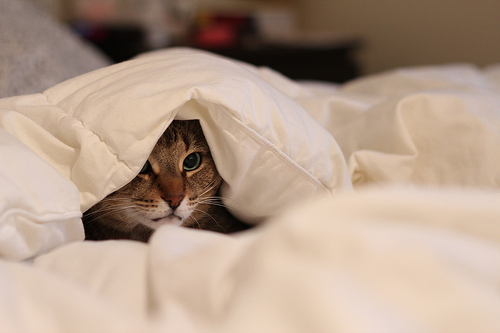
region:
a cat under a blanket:
[90, 107, 237, 230]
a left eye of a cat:
[181, 147, 203, 172]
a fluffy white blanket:
[15, 62, 488, 227]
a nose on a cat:
[163, 192, 188, 205]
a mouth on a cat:
[146, 208, 181, 225]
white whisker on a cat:
[88, 195, 138, 230]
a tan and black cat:
[96, 113, 228, 233]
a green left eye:
[181, 145, 206, 173]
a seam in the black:
[46, 80, 96, 160]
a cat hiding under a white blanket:
[0, 60, 489, 324]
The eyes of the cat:
[135, 153, 220, 188]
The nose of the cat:
[165, 183, 179, 204]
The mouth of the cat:
[157, 211, 188, 221]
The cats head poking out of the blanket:
[85, 135, 239, 220]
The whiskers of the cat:
[97, 195, 217, 216]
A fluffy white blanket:
[5, 68, 429, 330]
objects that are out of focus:
[46, 2, 348, 110]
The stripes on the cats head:
[159, 133, 196, 143]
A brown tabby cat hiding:
[109, 148, 234, 246]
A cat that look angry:
[73, 131, 248, 251]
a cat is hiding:
[81, 118, 253, 241]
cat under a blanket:
[81, 118, 255, 242]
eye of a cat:
[183, 148, 203, 171]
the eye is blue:
[182, 148, 204, 174]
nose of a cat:
[165, 194, 183, 204]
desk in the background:
[170, 36, 365, 82]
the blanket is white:
[0, 49, 495, 329]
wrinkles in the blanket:
[348, 65, 496, 180]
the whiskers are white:
[192, 179, 226, 223]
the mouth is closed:
[150, 209, 185, 223]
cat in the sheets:
[99, 84, 265, 239]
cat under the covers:
[55, 89, 296, 259]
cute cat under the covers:
[46, 75, 332, 278]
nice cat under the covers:
[42, 82, 302, 256]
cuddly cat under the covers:
[32, 66, 307, 281]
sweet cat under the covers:
[52, 72, 292, 276]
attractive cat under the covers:
[37, 95, 287, 282]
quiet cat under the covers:
[55, 75, 300, 274]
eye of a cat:
[166, 146, 215, 184]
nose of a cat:
[151, 178, 191, 220]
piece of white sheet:
[258, 239, 426, 311]